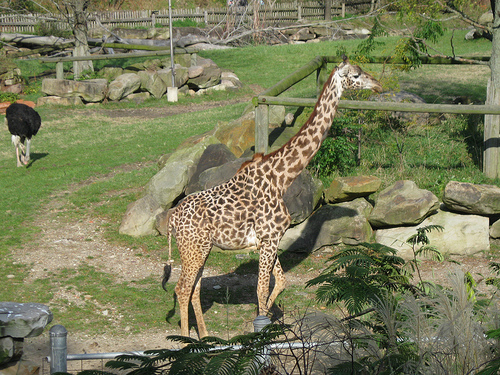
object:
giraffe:
[162, 54, 386, 344]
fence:
[1, 0, 383, 34]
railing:
[253, 46, 500, 179]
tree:
[335, 0, 499, 181]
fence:
[47, 315, 500, 375]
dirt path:
[1, 83, 500, 375]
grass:
[0, 27, 500, 336]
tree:
[0, 0, 133, 81]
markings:
[211, 199, 268, 237]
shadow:
[166, 197, 360, 337]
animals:
[5, 101, 41, 168]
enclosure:
[1, 0, 500, 375]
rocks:
[441, 179, 500, 216]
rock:
[278, 197, 376, 253]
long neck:
[284, 71, 344, 191]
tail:
[160, 262, 172, 292]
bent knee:
[273, 274, 287, 291]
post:
[49, 324, 67, 374]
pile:
[37, 52, 241, 106]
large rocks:
[40, 78, 107, 102]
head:
[336, 53, 384, 94]